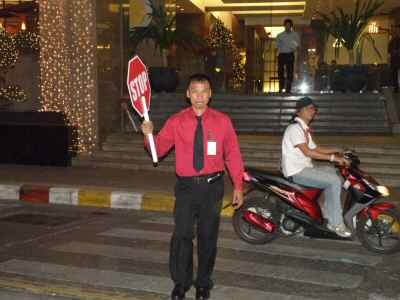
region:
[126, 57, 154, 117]
red and white stop sign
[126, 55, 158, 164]
stop sign on stick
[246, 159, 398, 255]
red and black motorcycle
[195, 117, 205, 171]
black cotton neck tie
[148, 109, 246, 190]
red button down shirt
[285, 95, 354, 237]
man sitting on motorcycle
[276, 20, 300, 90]
man walking down steps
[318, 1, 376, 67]
palm tree in pot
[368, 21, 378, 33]
light fixture on wall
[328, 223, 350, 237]
white and blue sneakers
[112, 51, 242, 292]
A man holding a stop sign.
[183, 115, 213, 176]
The man is wearing a black tie.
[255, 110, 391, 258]
A person on the motorcycle.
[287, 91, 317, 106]
The man is wearing a hat.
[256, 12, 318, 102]
A man walking out of the building.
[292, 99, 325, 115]
The person is wearing glasses.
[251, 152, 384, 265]
The bike is red.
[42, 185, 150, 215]
The edge of sidewalk is red white and yellow.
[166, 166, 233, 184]
The man wearing a black belt.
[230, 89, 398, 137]
Steps in front of the building.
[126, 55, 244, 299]
the man standing in the sidewalk and holding a STOP sign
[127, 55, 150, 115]
the red STOP sign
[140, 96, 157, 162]
the white handle to the STOP sign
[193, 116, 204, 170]
the man's long tie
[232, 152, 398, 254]
the motorcycle on the road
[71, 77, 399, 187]
the stairs to the building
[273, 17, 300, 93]
the man standing above the stairs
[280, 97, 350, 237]
the man sitting on the motorcycle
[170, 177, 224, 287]
the long black pants on the man standing in the crosswalk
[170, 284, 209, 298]
the dark dress shoes on the man's feet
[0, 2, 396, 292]
Exterior shot, nighttime.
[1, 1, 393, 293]
Depiction of exterior of lavish facility, possibly during holidays. y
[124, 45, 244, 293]
Man, holding small stop sign in right hand.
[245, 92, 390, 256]
Casually dressed man, on expensive-looking red motorcycle.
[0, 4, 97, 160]
Shrubbery with lights and glittery column, outside building.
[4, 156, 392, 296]
Crosswalk and curb with demarcations in yellow, white and red.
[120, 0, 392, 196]
Steps leading to glassed-in entrance of building.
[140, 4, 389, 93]
Luxurious looking lobby, with exotic plants, and decorative rafters on ceiling.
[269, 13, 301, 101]
Man, standing in lobby.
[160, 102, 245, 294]
Pink shirt, black pants, tie and tag, on crosswalk man.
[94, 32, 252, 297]
a man holding a stop sign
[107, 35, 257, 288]
a man with a red shirt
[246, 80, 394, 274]
a man on a motorcycle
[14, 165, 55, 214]
a red block on the curb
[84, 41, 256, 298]
a man with a black tie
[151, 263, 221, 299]
black dress shoes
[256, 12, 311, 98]
a man walking down the stairs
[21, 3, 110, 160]
lights on a post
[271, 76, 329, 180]
a man with a hat on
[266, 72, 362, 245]
a man with blue jeans on